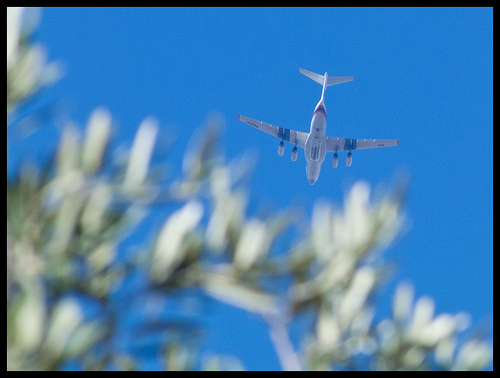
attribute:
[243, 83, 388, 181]
plane — blue, red, white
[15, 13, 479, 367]
sky — section, blue, clear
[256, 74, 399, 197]
airplane — in air, blue, white, preparing to land, flying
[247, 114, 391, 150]
wings — these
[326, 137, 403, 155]
wing — long, blue, white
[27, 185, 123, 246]
leaves — green, blurry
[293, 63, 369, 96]
wing — back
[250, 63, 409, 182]
jet — flying, preparing to land